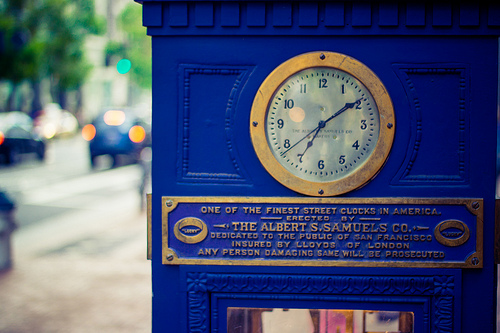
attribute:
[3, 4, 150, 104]
trees — blurry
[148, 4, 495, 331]
object — blue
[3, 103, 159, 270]
cars — blurry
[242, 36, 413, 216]
clock — gold, black, white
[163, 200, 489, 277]
letters — gold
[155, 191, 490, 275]
blue/gold plaque — blue, gold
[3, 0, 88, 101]
tree — distant, green, large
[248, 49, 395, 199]
rim — gold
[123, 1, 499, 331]
structure — blue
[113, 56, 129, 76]
light — green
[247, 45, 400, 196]
trim — gold